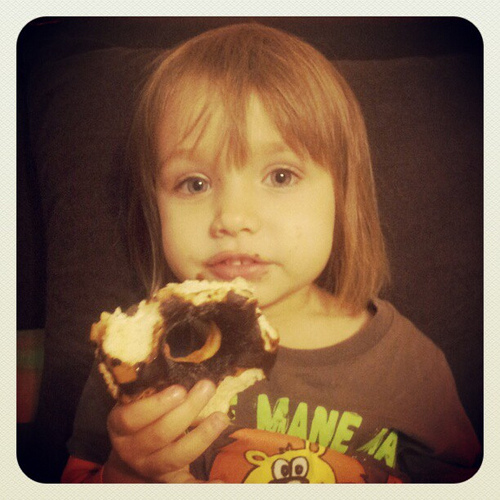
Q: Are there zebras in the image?
A: No, there are no zebras.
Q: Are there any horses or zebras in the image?
A: No, there are no zebras or horses.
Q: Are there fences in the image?
A: No, there are no fences.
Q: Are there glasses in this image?
A: No, there are no glasses.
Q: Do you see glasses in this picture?
A: No, there are no glasses.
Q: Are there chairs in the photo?
A: Yes, there is a chair.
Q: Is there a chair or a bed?
A: Yes, there is a chair.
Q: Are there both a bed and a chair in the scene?
A: No, there is a chair but no beds.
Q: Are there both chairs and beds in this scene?
A: No, there is a chair but no beds.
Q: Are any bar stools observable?
A: No, there are no bar stools.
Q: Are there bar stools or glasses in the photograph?
A: No, there are no bar stools or glasses.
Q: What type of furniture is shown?
A: The furniture is a chair.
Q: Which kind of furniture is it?
A: The piece of furniture is a chair.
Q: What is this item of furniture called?
A: That is a chair.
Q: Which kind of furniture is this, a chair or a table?
A: That is a chair.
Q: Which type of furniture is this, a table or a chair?
A: That is a chair.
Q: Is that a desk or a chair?
A: That is a chair.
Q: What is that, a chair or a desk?
A: That is a chair.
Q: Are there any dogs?
A: No, there are no dogs.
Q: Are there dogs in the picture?
A: No, there are no dogs.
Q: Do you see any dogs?
A: No, there are no dogs.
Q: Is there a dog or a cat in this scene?
A: No, there are no dogs or cats.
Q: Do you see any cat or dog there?
A: No, there are no dogs or cats.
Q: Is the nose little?
A: Yes, the nose is little.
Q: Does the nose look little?
A: Yes, the nose is little.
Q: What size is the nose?
A: The nose is little.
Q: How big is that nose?
A: The nose is little.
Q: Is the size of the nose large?
A: No, the nose is little.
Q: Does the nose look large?
A: No, the nose is little.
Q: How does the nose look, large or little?
A: The nose is little.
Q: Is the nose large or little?
A: The nose is little.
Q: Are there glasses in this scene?
A: No, there are no glasses.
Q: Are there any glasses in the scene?
A: No, there are no glasses.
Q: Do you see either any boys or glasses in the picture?
A: No, there are no glasses or boys.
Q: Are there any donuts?
A: Yes, there is a donut.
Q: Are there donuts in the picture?
A: Yes, there is a donut.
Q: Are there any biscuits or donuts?
A: Yes, there is a donut.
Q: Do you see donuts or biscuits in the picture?
A: Yes, there is a donut.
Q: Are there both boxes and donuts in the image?
A: No, there is a donut but no boxes.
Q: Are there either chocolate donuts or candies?
A: Yes, there is a chocolate donut.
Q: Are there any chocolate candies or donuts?
A: Yes, there is a chocolate donut.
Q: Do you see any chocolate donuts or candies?
A: Yes, there is a chocolate donut.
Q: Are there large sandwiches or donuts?
A: Yes, there is a large donut.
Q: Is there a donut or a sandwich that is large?
A: Yes, the donut is large.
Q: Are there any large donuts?
A: Yes, there is a large donut.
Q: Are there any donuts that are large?
A: Yes, there is a donut that is large.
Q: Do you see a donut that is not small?
A: Yes, there is a large donut.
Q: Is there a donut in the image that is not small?
A: Yes, there is a large donut.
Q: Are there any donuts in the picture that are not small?
A: Yes, there is a large donut.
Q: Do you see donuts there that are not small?
A: Yes, there is a large donut.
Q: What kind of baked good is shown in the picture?
A: The baked good is a donut.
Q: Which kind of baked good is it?
A: The food is a donut.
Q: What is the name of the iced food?
A: The food is a donut.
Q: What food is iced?
A: The food is a donut.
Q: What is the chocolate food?
A: The food is a donut.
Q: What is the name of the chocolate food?
A: The food is a donut.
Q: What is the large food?
A: The food is a donut.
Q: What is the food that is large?
A: The food is a donut.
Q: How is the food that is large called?
A: The food is a donut.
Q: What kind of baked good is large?
A: The baked good is a donut.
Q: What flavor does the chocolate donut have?
A: That is a chocolate donut.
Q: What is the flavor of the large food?
A: That is a chocolate donut.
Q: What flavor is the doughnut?
A: That is a chocolate donut.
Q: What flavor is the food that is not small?
A: That is a chocolate donut.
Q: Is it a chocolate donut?
A: Yes, that is a chocolate donut.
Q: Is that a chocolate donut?
A: Yes, that is a chocolate donut.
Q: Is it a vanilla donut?
A: No, that is a chocolate donut.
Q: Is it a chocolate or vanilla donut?
A: That is a chocolate donut.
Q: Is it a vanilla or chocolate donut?
A: That is a chocolate donut.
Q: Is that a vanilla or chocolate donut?
A: That is a chocolate donut.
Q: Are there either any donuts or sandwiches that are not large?
A: No, there is a donut but it is large.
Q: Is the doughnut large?
A: Yes, the doughnut is large.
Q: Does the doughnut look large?
A: Yes, the doughnut is large.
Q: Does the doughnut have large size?
A: Yes, the doughnut is large.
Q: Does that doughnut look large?
A: Yes, the doughnut is large.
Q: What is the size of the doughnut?
A: The doughnut is large.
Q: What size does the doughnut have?
A: The doughnut has large size.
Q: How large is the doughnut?
A: The doughnut is large.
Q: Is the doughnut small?
A: No, the doughnut is large.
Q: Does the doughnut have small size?
A: No, the doughnut is large.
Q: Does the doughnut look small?
A: No, the doughnut is large.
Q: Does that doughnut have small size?
A: No, the doughnut is large.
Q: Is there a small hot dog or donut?
A: No, there is a donut but it is large.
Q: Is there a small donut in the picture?
A: No, there is a donut but it is large.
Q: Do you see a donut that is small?
A: No, there is a donut but it is large.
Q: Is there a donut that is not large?
A: No, there is a donut but it is large.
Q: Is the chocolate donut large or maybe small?
A: The doughnut is large.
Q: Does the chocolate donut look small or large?
A: The doughnut is large.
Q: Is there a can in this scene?
A: No, there are no cans.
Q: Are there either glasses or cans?
A: No, there are no cans or glasses.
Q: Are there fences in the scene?
A: No, there are no fences.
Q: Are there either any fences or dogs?
A: No, there are no fences or dogs.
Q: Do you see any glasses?
A: No, there are no glasses.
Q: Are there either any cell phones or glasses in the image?
A: No, there are no glasses or cell phones.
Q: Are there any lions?
A: Yes, there is a lion.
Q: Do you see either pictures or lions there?
A: Yes, there is a lion.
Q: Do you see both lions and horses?
A: No, there is a lion but no horses.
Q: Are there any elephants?
A: No, there are no elephants.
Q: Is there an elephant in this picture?
A: No, there are no elephants.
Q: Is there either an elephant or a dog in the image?
A: No, there are no elephants or dogs.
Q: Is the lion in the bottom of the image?
A: Yes, the lion is in the bottom of the image.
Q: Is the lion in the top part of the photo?
A: No, the lion is in the bottom of the image.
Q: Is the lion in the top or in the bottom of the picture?
A: The lion is in the bottom of the image.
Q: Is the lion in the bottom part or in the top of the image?
A: The lion is in the bottom of the image.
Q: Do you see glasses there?
A: No, there are no glasses.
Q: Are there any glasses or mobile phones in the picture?
A: No, there are no glasses or mobile phones.